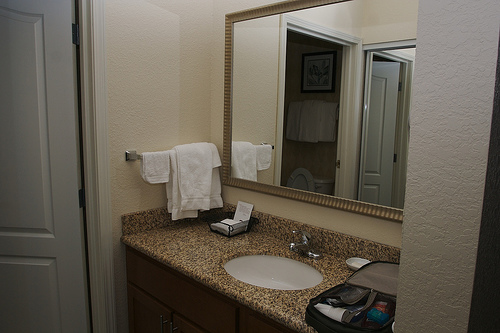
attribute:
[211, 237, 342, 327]
basin — white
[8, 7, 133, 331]
door — open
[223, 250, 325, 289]
sink — oval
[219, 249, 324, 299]
sink — white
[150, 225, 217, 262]
mosaic slab — white, dotted, brown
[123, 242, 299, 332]
shelves — wooden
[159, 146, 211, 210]
towels — white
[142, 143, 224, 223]
towel — white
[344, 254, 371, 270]
soap container — white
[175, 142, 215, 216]
towel — white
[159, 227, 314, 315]
top — counter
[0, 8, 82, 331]
door — white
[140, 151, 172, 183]
face cloth — white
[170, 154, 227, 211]
towels — white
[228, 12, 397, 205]
mirror — large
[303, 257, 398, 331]
bag — black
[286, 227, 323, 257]
faucet — metal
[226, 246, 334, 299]
sink — white, ceramic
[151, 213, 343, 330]
counter — marble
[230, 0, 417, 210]
mirror — large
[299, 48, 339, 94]
picture — framed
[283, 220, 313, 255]
tap — steel